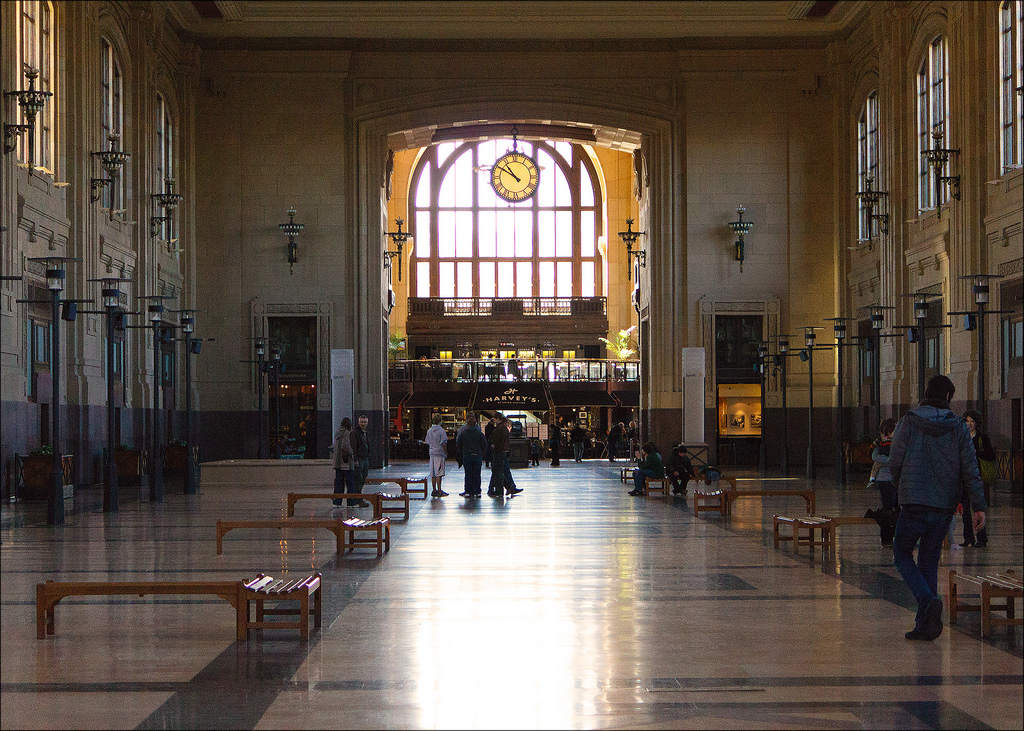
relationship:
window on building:
[475, 255, 542, 305] [19, 5, 1007, 716]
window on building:
[530, 135, 580, 209] [19, 5, 1007, 716]